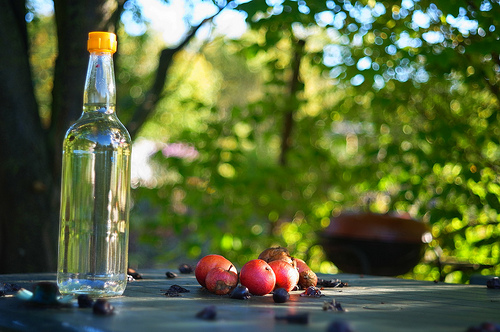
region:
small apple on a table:
[202, 261, 239, 293]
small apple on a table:
[192, 248, 234, 287]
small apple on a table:
[243, 255, 279, 295]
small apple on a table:
[267, 256, 302, 288]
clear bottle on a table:
[45, 21, 139, 304]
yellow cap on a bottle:
[84, 27, 120, 57]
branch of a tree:
[110, 8, 225, 153]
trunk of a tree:
[259, 25, 322, 262]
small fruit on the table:
[174, 255, 197, 275]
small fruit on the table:
[267, 284, 295, 305]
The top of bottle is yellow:
[78, 25, 142, 46]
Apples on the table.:
[198, 241, 322, 282]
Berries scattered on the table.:
[154, 273, 346, 323]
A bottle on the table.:
[68, 37, 143, 289]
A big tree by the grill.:
[196, 57, 482, 216]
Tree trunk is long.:
[18, 33, 73, 245]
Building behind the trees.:
[137, 131, 244, 236]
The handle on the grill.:
[351, 180, 406, 212]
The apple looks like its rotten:
[213, 269, 240, 294]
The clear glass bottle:
[49, 17, 140, 301]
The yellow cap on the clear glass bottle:
[84, 26, 122, 53]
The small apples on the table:
[184, 240, 319, 297]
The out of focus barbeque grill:
[297, 180, 437, 278]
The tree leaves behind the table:
[30, 0, 498, 284]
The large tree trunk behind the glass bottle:
[3, 2, 123, 269]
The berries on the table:
[5, 260, 356, 328]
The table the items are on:
[0, 265, 499, 330]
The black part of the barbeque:
[312, 231, 430, 276]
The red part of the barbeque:
[321, 207, 441, 243]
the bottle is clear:
[43, 15, 180, 330]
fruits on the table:
[176, 213, 373, 329]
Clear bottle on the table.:
[55, 26, 133, 297]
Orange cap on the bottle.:
[83, 27, 118, 52]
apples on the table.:
[196, 247, 311, 294]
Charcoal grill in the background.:
[310, 187, 433, 282]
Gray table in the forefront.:
[0, 260, 497, 325]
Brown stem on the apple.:
[225, 260, 233, 272]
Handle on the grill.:
[356, 188, 401, 219]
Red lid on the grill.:
[320, 185, 430, 245]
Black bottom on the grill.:
[310, 227, 426, 277]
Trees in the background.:
[1, 2, 498, 280]